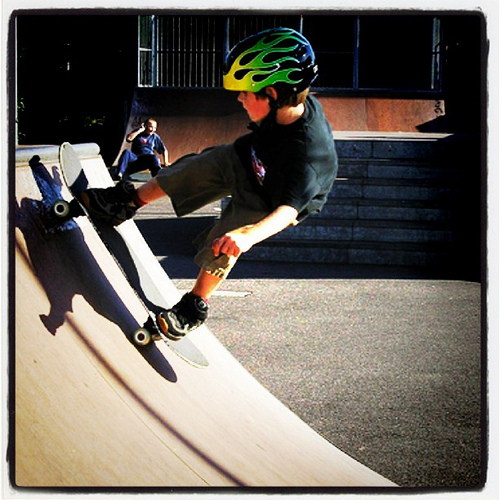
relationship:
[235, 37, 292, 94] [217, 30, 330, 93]
flame on helmet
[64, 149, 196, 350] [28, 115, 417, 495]
skateboard on ramp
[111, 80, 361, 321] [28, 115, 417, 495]
child on ramp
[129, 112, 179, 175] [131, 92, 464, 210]
skater on ramp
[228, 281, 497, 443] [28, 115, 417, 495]
pavement near ramp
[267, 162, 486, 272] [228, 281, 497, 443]
steps near pavement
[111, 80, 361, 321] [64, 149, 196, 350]
child on skateboard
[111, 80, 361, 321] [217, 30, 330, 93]
child has helmet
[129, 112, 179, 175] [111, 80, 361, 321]
skater watching child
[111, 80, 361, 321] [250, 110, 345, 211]
child wears shirt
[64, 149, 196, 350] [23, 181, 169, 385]
skateboard has shadow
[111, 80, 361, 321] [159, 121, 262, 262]
child has shorts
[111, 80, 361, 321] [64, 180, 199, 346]
child has shoes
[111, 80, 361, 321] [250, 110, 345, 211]
child has shirt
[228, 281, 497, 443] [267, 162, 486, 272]
pavement below steps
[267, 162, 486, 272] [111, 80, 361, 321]
steps behind child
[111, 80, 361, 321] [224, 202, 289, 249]
child has arm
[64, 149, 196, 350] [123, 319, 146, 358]
skateboard has wheels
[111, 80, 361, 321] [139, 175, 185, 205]
child has leg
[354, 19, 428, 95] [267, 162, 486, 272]
window behind steps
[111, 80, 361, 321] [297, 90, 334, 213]
child has back